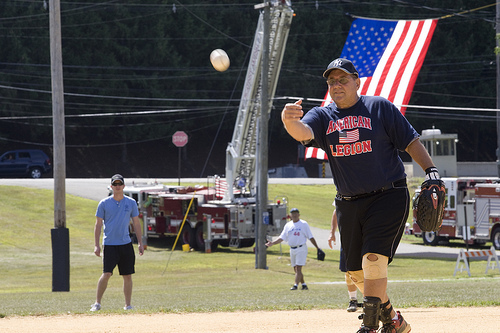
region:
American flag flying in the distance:
[305, 12, 435, 163]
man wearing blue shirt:
[89, 170, 144, 312]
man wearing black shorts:
[89, 175, 139, 314]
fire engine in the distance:
[121, 173, 286, 256]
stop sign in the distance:
[170, 128, 192, 187]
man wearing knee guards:
[357, 245, 409, 325]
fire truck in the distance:
[417, 178, 499, 243]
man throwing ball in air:
[207, 46, 448, 323]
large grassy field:
[0, 187, 96, 304]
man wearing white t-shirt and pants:
[278, 203, 315, 291]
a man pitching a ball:
[198, 38, 460, 239]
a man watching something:
[83, 169, 148, 310]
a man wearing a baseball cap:
[105, 172, 127, 201]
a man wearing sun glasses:
[106, 170, 128, 205]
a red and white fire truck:
[126, 177, 286, 257]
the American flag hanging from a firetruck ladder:
[223, 8, 451, 58]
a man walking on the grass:
[265, 205, 328, 299]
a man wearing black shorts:
[78, 166, 149, 314]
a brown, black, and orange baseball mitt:
[413, 174, 448, 238]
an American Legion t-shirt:
[304, 99, 411, 198]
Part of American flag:
[349, 16, 418, 70]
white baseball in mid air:
[207, 44, 235, 75]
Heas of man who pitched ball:
[322, 58, 363, 104]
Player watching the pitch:
[90, 170, 148, 312]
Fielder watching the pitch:
[267, 204, 326, 289]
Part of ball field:
[165, 271, 234, 299]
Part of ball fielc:
[12, 199, 46, 231]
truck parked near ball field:
[412, 182, 498, 242]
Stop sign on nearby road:
[171, 125, 191, 187]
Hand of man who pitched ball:
[277, 97, 307, 132]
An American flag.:
[304, 7, 434, 158]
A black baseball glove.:
[412, 179, 448, 230]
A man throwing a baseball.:
[194, 37, 465, 330]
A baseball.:
[209, 46, 229, 71]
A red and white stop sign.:
[172, 129, 190, 149]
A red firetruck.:
[110, 179, 295, 251]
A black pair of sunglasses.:
[111, 181, 123, 187]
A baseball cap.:
[324, 61, 363, 76]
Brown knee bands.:
[345, 253, 391, 290]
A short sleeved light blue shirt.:
[97, 196, 139, 245]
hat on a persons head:
[319, 55, 365, 82]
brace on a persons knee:
[357, 247, 394, 282]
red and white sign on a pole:
[169, 127, 192, 150]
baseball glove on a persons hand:
[410, 174, 454, 236]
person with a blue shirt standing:
[82, 167, 152, 320]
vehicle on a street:
[0, 142, 53, 182]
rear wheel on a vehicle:
[24, 162, 44, 181]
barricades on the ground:
[452, 245, 499, 280]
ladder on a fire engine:
[202, 1, 302, 206]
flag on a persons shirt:
[332, 124, 365, 147]